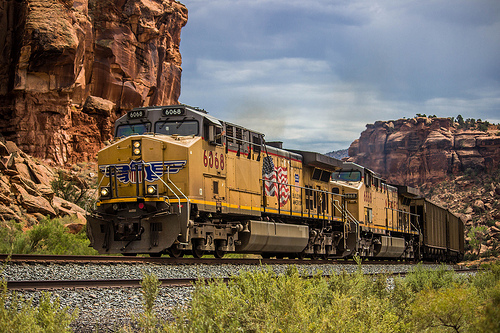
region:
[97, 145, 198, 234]
American eagle on front of train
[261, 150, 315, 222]
american flag painted on side of train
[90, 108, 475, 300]
A train rolling down the tracks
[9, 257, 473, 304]
The gravel in between the train tracks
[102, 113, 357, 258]
The engine of the train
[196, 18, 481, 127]
Blue sky with some clouds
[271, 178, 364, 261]
Steps to walk up on the engine of the train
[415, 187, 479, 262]
A brown rail car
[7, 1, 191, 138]
Red mountains beside the train tracks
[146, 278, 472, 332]
Prairie brush growing next to the train tracks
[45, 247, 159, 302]
These are train tracks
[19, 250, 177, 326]
The tracks have rust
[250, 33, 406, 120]
These are lots of clouds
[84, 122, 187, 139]
These are windows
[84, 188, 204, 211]
These are white lights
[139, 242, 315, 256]
These are small wheels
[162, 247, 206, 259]
The wheels are made of steel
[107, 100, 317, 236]
The train is mustard yellow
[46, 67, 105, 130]
This is a canyon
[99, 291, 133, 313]
These are little rocks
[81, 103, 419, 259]
Yellow train going down the railroad tracks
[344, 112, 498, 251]
Rock formation in back of the train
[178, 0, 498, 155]
Blue sky with white clouds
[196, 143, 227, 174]
Red number on the left side of the train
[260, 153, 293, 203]
American flag on the left side of the train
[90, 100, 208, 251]
Front of the yellow train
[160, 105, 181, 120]
White numbers at the top front of the train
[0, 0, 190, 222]
Rock formation on the side of the train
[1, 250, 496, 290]
Railroad tracks the train is on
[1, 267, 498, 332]
Bushes on the side of the railroad tracks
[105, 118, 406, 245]
yellow train car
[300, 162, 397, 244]
yelow train car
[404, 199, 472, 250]
black train car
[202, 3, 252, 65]
white clouds in blue sky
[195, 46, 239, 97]
white clouds in blue sky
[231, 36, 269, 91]
white clouds in blue sky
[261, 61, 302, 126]
white clouds in blue sky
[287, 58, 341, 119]
white clouds in blue sky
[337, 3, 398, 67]
white clouds in blue sky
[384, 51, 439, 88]
white clouds in blue sky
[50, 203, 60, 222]
part of a rock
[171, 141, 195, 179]
part of a train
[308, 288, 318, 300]
part of a bush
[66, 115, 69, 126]
edge of a rock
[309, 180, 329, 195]
side of a train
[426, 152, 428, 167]
side of a hill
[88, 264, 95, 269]
part of a rock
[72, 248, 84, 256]
edge of a rail way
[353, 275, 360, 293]
part of the bush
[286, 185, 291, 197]
side of a train